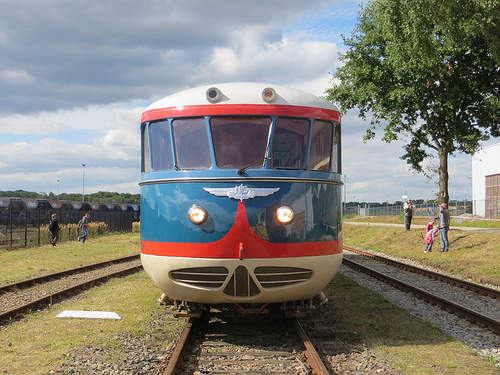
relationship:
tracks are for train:
[1, 244, 497, 374] [140, 82, 345, 322]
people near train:
[46, 193, 453, 255] [140, 82, 345, 322]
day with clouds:
[0, 3, 498, 373] [0, 1, 499, 197]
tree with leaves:
[331, 3, 500, 230] [329, 3, 499, 154]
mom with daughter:
[437, 202, 452, 254] [421, 221, 435, 254]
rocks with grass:
[55, 309, 376, 374] [5, 250, 500, 374]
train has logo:
[140, 82, 345, 322] [204, 184, 282, 203]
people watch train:
[46, 193, 453, 255] [140, 82, 345, 322]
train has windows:
[140, 82, 345, 322] [138, 120, 340, 173]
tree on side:
[331, 3, 500, 230] [492, 2, 500, 375]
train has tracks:
[140, 82, 345, 322] [1, 244, 497, 374]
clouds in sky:
[0, 1, 499, 197] [0, 1, 315, 80]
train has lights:
[140, 82, 345, 322] [189, 203, 296, 226]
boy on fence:
[47, 210, 60, 245] [0, 201, 133, 249]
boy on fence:
[75, 211, 91, 247] [0, 201, 133, 249]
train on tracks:
[140, 82, 345, 322] [1, 244, 497, 374]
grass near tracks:
[5, 250, 500, 374] [1, 244, 497, 374]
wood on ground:
[52, 307, 120, 319] [3, 217, 500, 374]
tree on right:
[331, 3, 500, 230] [492, 2, 500, 375]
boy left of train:
[47, 210, 60, 245] [140, 82, 345, 322]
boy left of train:
[75, 211, 91, 247] [140, 82, 345, 322]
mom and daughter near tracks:
[422, 201, 450, 255] [1, 244, 497, 374]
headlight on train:
[186, 205, 209, 225] [140, 82, 345, 322]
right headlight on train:
[276, 204, 298, 227] [140, 82, 345, 322]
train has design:
[140, 82, 345, 322] [150, 256, 321, 306]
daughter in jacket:
[421, 221, 435, 254] [426, 229, 435, 243]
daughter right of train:
[421, 221, 435, 254] [140, 82, 345, 322]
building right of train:
[468, 140, 499, 222] [140, 82, 345, 322]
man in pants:
[403, 198, 414, 231] [404, 214, 412, 231]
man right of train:
[403, 198, 414, 231] [140, 82, 345, 322]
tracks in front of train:
[1, 244, 497, 374] [140, 82, 345, 322]